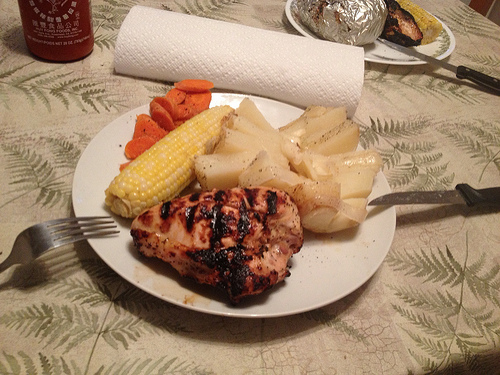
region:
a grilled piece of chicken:
[130, 187, 302, 297]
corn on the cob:
[106, 106, 234, 218]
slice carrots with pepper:
[119, 78, 212, 172]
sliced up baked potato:
[194, 98, 381, 233]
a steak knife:
[366, 183, 498, 206]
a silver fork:
[0, 215, 119, 272]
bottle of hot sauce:
[18, 0, 93, 62]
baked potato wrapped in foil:
[290, 0, 386, 45]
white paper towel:
[112, 5, 364, 112]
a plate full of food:
[70, 91, 395, 313]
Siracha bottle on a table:
[8, 0, 113, 110]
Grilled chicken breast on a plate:
[106, 186, 333, 350]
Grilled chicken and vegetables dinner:
[113, 77, 363, 322]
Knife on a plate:
[342, 162, 474, 255]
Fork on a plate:
[0, 197, 130, 289]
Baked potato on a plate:
[292, 2, 398, 75]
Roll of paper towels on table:
[93, 8, 393, 126]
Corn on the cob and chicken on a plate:
[388, 0, 457, 89]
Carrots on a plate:
[108, 45, 208, 155]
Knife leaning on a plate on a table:
[393, 27, 483, 140]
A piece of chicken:
[129, 183, 301, 301]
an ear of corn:
[101, 105, 234, 218]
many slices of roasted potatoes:
[195, 93, 381, 233]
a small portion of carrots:
[119, 77, 213, 172]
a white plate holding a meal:
[71, 91, 397, 320]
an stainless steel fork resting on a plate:
[0, 216, 122, 273]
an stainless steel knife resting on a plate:
[368, 182, 498, 209]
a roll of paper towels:
[111, 4, 363, 119]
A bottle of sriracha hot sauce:
[20, 0, 94, 63]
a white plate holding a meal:
[284, 0, 456, 67]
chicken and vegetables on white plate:
[59, 74, 411, 307]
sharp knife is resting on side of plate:
[354, 171, 496, 229]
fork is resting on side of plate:
[6, 195, 110, 293]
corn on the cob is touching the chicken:
[109, 100, 236, 220]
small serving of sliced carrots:
[117, 75, 207, 150]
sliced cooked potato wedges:
[219, 102, 371, 220]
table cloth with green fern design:
[403, 242, 471, 338]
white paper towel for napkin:
[108, 2, 358, 117]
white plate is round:
[51, 59, 426, 331]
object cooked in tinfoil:
[291, 1, 395, 44]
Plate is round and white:
[70, 89, 398, 320]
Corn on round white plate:
[102, 100, 239, 220]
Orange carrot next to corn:
[173, 75, 213, 94]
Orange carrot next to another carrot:
[177, 76, 217, 92]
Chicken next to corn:
[120, 181, 304, 306]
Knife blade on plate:
[365, 175, 499, 212]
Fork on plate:
[0, 208, 124, 270]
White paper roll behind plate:
[109, 6, 365, 118]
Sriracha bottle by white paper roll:
[15, 0, 96, 62]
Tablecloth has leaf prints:
[0, 0, 498, 372]